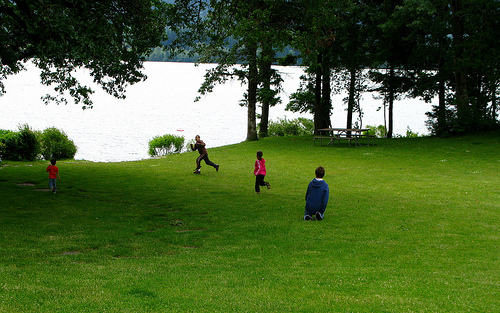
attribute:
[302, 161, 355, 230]
boy — leaning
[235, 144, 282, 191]
girl — running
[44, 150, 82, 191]
boy — running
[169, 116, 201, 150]
frisbee — flying, here, played, white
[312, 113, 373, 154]
table — unused, empty, brown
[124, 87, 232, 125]
water — here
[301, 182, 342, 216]
sweater — blue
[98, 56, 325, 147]
lake — here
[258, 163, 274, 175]
jacket — pink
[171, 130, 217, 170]
man — catching, running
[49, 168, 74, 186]
shirt — red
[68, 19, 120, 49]
leaves — green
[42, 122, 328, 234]
people — playing, standing, four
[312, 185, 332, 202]
sweatshirt — blue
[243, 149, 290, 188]
child — running, wearing, going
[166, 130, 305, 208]
children — playing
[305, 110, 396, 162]
tables — picnic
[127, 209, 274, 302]
grass — green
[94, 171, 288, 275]
field — grassy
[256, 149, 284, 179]
sweater — pink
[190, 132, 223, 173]
outfit — brown